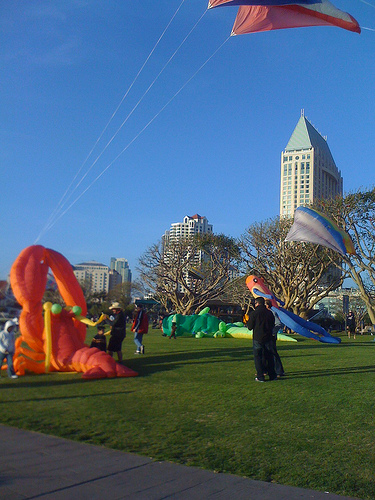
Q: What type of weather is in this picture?
A: It is clear.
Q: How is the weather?
A: It is clear.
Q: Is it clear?
A: Yes, it is clear.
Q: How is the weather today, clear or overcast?
A: It is clear.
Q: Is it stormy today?
A: No, it is clear.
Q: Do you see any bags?
A: No, there are no bags.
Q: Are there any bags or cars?
A: No, there are no bags or cars.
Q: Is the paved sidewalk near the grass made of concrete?
A: Yes, the sidewalk is made of concrete.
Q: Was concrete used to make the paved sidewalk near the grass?
A: Yes, the sidewalk is made of concrete.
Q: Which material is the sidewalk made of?
A: The sidewalk is made of cement.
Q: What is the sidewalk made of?
A: The sidewalk is made of concrete.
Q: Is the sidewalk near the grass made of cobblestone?
A: No, the sidewalk is made of concrete.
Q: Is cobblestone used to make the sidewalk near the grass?
A: No, the sidewalk is made of concrete.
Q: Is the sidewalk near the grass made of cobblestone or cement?
A: The side walk is made of cement.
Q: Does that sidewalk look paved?
A: Yes, the sidewalk is paved.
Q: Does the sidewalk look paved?
A: Yes, the sidewalk is paved.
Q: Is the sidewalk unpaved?
A: No, the sidewalk is paved.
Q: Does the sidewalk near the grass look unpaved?
A: No, the side walk is paved.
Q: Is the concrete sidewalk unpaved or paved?
A: The side walk is paved.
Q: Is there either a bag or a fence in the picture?
A: No, there are no fences or bags.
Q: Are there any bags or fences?
A: No, there are no fences or bags.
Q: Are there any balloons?
A: Yes, there is a balloon.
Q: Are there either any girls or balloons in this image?
A: Yes, there is a balloon.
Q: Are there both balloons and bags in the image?
A: No, there is a balloon but no bags.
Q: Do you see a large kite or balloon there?
A: Yes, there is a large balloon.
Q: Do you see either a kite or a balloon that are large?
A: Yes, the balloon is large.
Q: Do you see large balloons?
A: Yes, there is a large balloon.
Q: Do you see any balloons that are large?
A: Yes, there is a balloon that is large.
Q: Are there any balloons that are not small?
A: Yes, there is a large balloon.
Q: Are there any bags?
A: No, there are no bags.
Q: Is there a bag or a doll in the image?
A: No, there are no bags or dolls.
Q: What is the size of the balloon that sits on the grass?
A: The balloon is large.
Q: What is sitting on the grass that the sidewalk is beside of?
A: The balloon is sitting on the grass.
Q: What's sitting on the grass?
A: The balloon is sitting on the grass.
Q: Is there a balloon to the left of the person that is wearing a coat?
A: Yes, there is a balloon to the left of the person.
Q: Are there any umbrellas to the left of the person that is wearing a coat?
A: No, there is a balloon to the left of the person.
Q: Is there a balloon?
A: Yes, there is a balloon.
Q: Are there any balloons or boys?
A: Yes, there is a balloon.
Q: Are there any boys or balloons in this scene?
A: Yes, there is a balloon.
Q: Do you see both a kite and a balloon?
A: Yes, there are both a balloon and a kite.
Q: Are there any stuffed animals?
A: No, there are no stuffed animals.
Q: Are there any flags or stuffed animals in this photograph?
A: No, there are no stuffed animals or flags.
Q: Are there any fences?
A: No, there are no fences.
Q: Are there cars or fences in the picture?
A: No, there are no fences or cars.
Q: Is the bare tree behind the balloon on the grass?
A: Yes, the tree is behind the balloon.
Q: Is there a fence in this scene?
A: No, there are no fences.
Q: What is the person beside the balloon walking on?
A: The person is walking on the grass.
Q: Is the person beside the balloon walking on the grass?
A: Yes, the person is walking on the grass.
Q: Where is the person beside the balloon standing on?
A: The person is standing on the grass.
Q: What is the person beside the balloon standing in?
A: The person is standing in the grass.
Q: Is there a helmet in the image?
A: No, there are no helmets.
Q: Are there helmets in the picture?
A: No, there are no helmets.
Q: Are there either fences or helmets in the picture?
A: No, there are no helmets or fences.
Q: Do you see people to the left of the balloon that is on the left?
A: Yes, there is a person to the left of the balloon.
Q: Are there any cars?
A: No, there are no cars.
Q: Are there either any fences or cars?
A: No, there are no cars or fences.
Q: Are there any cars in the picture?
A: No, there are no cars.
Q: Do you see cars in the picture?
A: No, there are no cars.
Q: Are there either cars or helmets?
A: No, there are no cars or helmets.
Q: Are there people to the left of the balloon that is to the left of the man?
A: Yes, there is a person to the left of the balloon.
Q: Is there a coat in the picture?
A: Yes, there is a coat.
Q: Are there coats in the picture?
A: Yes, there is a coat.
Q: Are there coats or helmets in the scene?
A: Yes, there is a coat.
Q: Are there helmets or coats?
A: Yes, there is a coat.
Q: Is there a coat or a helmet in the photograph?
A: Yes, there is a coat.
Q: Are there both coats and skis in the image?
A: No, there is a coat but no skis.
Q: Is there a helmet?
A: No, there are no helmets.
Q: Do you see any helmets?
A: No, there are no helmets.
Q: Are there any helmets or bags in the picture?
A: No, there are no helmets or bags.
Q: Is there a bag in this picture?
A: No, there are no bags.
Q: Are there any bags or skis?
A: No, there are no bags or skis.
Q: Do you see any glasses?
A: No, there are no glasses.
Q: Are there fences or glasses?
A: No, there are no glasses or fences.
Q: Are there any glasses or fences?
A: No, there are no glasses or fences.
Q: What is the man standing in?
A: The man is standing in the grass.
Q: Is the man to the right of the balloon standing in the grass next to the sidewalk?
A: Yes, the man is standing in the grass.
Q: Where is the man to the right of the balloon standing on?
A: The man is standing on the grass.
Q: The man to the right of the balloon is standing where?
A: The man is standing on the grass.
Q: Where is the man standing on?
A: The man is standing on the grass.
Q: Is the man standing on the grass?
A: Yes, the man is standing on the grass.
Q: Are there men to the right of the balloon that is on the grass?
A: Yes, there is a man to the right of the balloon.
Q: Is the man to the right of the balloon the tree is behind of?
A: Yes, the man is to the right of the balloon.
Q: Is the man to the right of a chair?
A: No, the man is to the right of the balloon.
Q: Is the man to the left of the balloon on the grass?
A: No, the man is to the right of the balloon.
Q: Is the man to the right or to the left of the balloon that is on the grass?
A: The man is to the right of the balloon.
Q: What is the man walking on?
A: The man is walking on the grass.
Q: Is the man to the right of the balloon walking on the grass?
A: Yes, the man is walking on the grass.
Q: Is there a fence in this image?
A: No, there are no fences.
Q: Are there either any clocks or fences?
A: No, there are no fences or clocks.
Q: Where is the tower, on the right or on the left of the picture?
A: The tower is on the right of the image.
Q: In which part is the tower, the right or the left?
A: The tower is on the right of the image.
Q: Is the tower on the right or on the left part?
A: The tower is on the right of the image.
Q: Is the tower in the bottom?
A: No, the tower is in the top of the image.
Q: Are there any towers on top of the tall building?
A: Yes, there is a tower on top of the building.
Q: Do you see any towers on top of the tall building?
A: Yes, there is a tower on top of the building.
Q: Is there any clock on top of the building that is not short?
A: No, there is a tower on top of the building.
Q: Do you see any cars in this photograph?
A: No, there are no cars.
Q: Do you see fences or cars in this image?
A: No, there are no cars or fences.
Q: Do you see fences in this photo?
A: No, there are no fences.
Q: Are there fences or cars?
A: No, there are no fences or cars.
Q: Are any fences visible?
A: No, there are no fences.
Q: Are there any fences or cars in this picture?
A: No, there are no fences or cars.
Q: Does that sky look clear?
A: Yes, the sky is clear.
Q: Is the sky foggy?
A: No, the sky is clear.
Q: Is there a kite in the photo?
A: Yes, there is a kite.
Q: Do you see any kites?
A: Yes, there is a kite.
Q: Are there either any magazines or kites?
A: Yes, there is a kite.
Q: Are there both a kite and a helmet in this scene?
A: No, there is a kite but no helmets.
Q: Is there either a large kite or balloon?
A: Yes, there is a large kite.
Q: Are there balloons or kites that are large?
A: Yes, the kite is large.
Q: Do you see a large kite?
A: Yes, there is a large kite.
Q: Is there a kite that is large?
A: Yes, there is a kite that is large.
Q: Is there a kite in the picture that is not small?
A: Yes, there is a large kite.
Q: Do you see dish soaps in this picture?
A: No, there are no dish soaps.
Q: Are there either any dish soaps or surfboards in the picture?
A: No, there are no dish soaps or surfboards.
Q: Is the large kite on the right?
A: Yes, the kite is on the right of the image.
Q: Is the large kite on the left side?
A: No, the kite is on the right of the image.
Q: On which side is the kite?
A: The kite is on the right of the image.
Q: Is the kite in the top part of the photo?
A: Yes, the kite is in the top of the image.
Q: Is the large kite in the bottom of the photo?
A: No, the kite is in the top of the image.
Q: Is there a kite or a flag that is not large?
A: No, there is a kite but it is large.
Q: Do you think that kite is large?
A: Yes, the kite is large.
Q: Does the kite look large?
A: Yes, the kite is large.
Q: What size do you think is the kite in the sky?
A: The kite is large.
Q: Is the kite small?
A: No, the kite is large.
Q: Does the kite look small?
A: No, the kite is large.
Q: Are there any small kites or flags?
A: No, there is a kite but it is large.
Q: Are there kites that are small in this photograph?
A: No, there is a kite but it is large.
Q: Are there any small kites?
A: No, there is a kite but it is large.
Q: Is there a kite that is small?
A: No, there is a kite but it is large.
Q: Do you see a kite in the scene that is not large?
A: No, there is a kite but it is large.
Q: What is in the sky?
A: The kite is in the sky.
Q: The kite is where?
A: The kite is in the sky.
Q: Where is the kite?
A: The kite is in the sky.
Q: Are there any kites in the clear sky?
A: Yes, there is a kite in the sky.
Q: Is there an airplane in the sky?
A: No, there is a kite in the sky.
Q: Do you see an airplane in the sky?
A: No, there is a kite in the sky.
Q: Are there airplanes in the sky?
A: No, there is a kite in the sky.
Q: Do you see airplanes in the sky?
A: No, there is a kite in the sky.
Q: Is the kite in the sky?
A: Yes, the kite is in the sky.